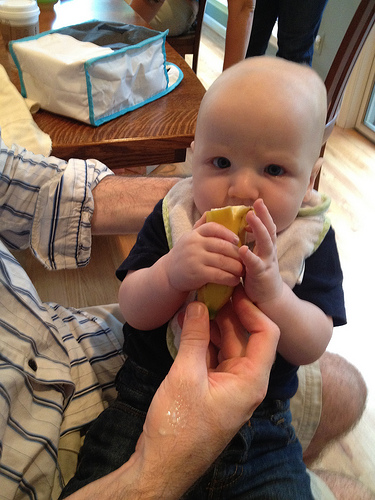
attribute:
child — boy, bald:
[72, 42, 351, 500]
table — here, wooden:
[4, 1, 221, 176]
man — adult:
[3, 143, 363, 500]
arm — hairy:
[90, 166, 194, 240]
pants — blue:
[247, 1, 331, 70]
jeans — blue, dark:
[75, 365, 314, 499]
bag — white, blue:
[4, 13, 188, 123]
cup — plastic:
[2, 3, 49, 76]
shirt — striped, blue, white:
[2, 132, 140, 490]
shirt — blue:
[104, 196, 346, 395]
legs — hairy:
[306, 353, 370, 499]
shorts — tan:
[288, 351, 330, 499]